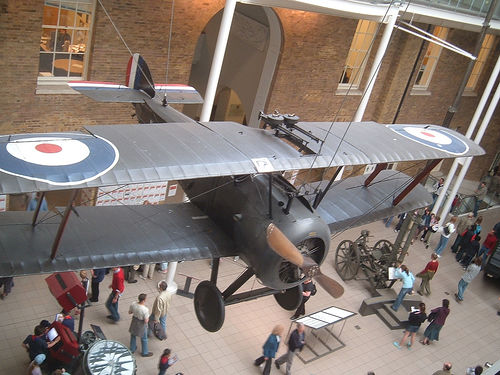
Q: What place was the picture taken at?
A: It was taken at the museum.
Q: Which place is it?
A: It is a museum.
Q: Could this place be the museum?
A: Yes, it is the museum.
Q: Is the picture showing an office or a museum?
A: It is showing a museum.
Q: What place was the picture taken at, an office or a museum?
A: It was taken at a museum.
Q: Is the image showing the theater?
A: No, the picture is showing the museum.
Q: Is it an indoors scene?
A: Yes, it is indoors.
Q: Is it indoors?
A: Yes, it is indoors.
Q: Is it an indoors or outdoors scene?
A: It is indoors.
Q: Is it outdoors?
A: No, it is indoors.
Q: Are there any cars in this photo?
A: No, there are no cars.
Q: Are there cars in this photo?
A: No, there are no cars.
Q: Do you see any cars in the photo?
A: No, there are no cars.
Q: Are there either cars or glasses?
A: No, there are no cars or glasses.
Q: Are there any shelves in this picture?
A: No, there are no shelves.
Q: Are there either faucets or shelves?
A: No, there are no shelves or faucets.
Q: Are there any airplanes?
A: Yes, there is an airplane.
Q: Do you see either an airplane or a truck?
A: Yes, there is an airplane.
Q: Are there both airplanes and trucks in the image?
A: No, there is an airplane but no trucks.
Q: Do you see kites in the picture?
A: No, there are no kites.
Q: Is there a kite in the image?
A: No, there are no kites.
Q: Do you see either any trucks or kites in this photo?
A: No, there are no kites or trucks.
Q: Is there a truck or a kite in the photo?
A: No, there are no kites or trucks.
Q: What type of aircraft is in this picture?
A: The aircraft is an airplane.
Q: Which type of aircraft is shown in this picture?
A: The aircraft is an airplane.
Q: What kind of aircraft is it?
A: The aircraft is an airplane.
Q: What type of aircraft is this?
A: That is an airplane.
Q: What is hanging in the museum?
A: The airplane is hanging in the museum.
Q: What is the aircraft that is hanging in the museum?
A: The aircraft is an airplane.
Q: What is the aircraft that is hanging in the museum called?
A: The aircraft is an airplane.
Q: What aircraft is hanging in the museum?
A: The aircraft is an airplane.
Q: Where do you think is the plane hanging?
A: The plane is hanging in the museum.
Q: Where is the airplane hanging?
A: The plane is hanging in the museum.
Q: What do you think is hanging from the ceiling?
A: The plane is hanging from the ceiling.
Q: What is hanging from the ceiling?
A: The plane is hanging from the ceiling.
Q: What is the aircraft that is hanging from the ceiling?
A: The aircraft is an airplane.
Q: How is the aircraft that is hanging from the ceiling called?
A: The aircraft is an airplane.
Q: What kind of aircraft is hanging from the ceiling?
A: The aircraft is an airplane.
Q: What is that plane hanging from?
A: The plane is hanging from the ceiling.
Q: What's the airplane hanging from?
A: The plane is hanging from the ceiling.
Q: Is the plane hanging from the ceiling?
A: Yes, the plane is hanging from the ceiling.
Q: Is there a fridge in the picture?
A: No, there are no refrigerators.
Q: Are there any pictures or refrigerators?
A: No, there are no refrigerators or pictures.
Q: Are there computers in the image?
A: No, there are no computers.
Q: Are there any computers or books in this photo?
A: No, there are no computers or books.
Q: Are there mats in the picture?
A: No, there are no mats.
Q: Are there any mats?
A: No, there are no mats.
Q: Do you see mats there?
A: No, there are no mats.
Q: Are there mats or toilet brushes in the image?
A: No, there are no mats or toilet brushes.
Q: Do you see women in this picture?
A: Yes, there is a woman.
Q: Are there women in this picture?
A: Yes, there is a woman.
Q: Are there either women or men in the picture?
A: Yes, there is a woman.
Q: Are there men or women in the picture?
A: Yes, there is a woman.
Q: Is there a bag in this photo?
A: No, there are no bags.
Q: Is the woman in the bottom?
A: Yes, the woman is in the bottom of the image.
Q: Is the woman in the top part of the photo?
A: No, the woman is in the bottom of the image.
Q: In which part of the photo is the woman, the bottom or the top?
A: The woman is in the bottom of the image.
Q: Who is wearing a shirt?
A: The woman is wearing a shirt.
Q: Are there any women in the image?
A: Yes, there is a woman.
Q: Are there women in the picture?
A: Yes, there is a woman.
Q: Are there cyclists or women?
A: Yes, there is a woman.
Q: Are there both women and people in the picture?
A: Yes, there are both a woman and a person.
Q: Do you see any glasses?
A: No, there are no glasses.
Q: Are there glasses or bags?
A: No, there are no glasses or bags.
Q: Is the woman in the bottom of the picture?
A: Yes, the woman is in the bottom of the image.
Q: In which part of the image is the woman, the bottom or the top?
A: The woman is in the bottom of the image.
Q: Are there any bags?
A: No, there are no bags.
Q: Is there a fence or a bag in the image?
A: No, there are no bags or fences.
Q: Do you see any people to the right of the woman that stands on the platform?
A: Yes, there is a person to the right of the woman.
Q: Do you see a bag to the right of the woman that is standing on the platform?
A: No, there is a person to the right of the woman.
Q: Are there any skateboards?
A: No, there are no skateboards.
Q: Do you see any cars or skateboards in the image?
A: No, there are no skateboards or cars.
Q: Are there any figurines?
A: No, there are no figurines.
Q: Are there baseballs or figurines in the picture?
A: No, there are no figurines or baseballs.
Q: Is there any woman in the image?
A: Yes, there is a woman.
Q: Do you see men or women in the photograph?
A: Yes, there is a woman.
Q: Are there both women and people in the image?
A: Yes, there are both a woman and a person.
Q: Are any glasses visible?
A: No, there are no glasses.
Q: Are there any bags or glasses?
A: No, there are no glasses or bags.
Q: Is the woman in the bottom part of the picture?
A: Yes, the woman is in the bottom of the image.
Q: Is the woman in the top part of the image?
A: No, the woman is in the bottom of the image.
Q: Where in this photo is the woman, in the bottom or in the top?
A: The woman is in the bottom of the image.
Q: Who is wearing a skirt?
A: The woman is wearing a skirt.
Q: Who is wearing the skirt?
A: The woman is wearing a skirt.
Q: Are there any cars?
A: No, there are no cars.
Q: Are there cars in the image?
A: No, there are no cars.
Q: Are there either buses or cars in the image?
A: No, there are no cars or buses.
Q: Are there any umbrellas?
A: No, there are no umbrellas.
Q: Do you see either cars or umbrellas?
A: No, there are no umbrellas or cars.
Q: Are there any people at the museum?
A: Yes, there are people at the museum.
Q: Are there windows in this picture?
A: Yes, there are windows.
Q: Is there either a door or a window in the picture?
A: Yes, there are windows.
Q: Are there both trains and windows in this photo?
A: No, there are windows but no trains.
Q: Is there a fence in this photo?
A: No, there are no fences.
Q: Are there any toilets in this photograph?
A: No, there are no toilets.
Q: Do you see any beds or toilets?
A: No, there are no toilets or beds.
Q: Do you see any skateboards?
A: No, there are no skateboards.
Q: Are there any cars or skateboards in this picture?
A: No, there are no skateboards or cars.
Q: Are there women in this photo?
A: Yes, there is a woman.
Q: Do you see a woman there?
A: Yes, there is a woman.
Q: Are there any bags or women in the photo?
A: Yes, there is a woman.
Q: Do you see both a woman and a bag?
A: No, there is a woman but no bags.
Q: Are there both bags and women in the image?
A: No, there is a woman but no bags.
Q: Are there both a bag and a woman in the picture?
A: No, there is a woman but no bags.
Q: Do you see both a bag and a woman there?
A: No, there is a woman but no bags.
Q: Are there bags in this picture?
A: No, there are no bags.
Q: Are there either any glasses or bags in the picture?
A: No, there are no bags or glasses.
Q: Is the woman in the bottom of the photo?
A: Yes, the woman is in the bottom of the image.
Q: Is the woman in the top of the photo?
A: No, the woman is in the bottom of the image.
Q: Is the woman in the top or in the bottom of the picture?
A: The woman is in the bottom of the image.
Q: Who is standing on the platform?
A: The woman is standing on the platform.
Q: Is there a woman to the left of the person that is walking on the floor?
A: Yes, there is a woman to the left of the person.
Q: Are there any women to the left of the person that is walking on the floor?
A: Yes, there is a woman to the left of the person.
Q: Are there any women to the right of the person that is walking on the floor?
A: No, the woman is to the left of the person.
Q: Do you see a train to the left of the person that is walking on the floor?
A: No, there is a woman to the left of the person.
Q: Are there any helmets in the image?
A: No, there are no helmets.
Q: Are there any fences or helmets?
A: No, there are no helmets or fences.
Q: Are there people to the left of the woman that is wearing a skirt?
A: Yes, there is a person to the left of the woman.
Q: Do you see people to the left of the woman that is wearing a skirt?
A: Yes, there is a person to the left of the woman.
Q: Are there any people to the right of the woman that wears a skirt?
A: No, the person is to the left of the woman.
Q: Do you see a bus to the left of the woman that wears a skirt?
A: No, there is a person to the left of the woman.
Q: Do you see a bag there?
A: No, there are no bags.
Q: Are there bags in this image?
A: No, there are no bags.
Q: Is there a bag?
A: No, there are no bags.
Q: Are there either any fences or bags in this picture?
A: No, there are no bags or fences.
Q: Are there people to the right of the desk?
A: Yes, there is a person to the right of the desk.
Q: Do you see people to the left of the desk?
A: No, the person is to the right of the desk.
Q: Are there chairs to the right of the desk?
A: No, there is a person to the right of the desk.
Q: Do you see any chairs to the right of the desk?
A: No, there is a person to the right of the desk.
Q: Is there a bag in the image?
A: No, there are no bags.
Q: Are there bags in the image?
A: No, there are no bags.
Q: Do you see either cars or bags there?
A: No, there are no bags or cars.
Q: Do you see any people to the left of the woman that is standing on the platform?
A: Yes, there is a person to the left of the woman.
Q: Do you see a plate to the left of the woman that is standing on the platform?
A: No, there is a person to the left of the woman.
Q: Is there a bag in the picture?
A: No, there are no bags.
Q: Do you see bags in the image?
A: No, there are no bags.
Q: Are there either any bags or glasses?
A: No, there are no bags or glasses.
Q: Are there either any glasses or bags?
A: No, there are no bags or glasses.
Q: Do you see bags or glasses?
A: No, there are no bags or glasses.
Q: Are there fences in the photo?
A: No, there are no fences.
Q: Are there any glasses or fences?
A: No, there are no fences or glasses.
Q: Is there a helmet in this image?
A: No, there are no helmets.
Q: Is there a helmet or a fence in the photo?
A: No, there are no helmets or fences.